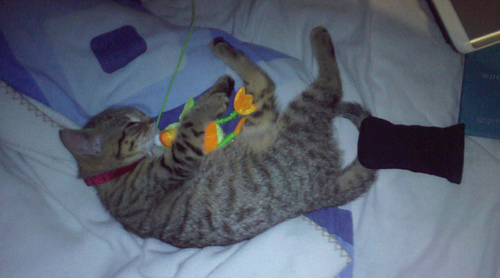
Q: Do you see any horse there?
A: No, there are no horses.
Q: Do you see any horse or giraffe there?
A: No, there are no horses or giraffes.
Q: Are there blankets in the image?
A: Yes, there is a blanket.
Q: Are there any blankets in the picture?
A: Yes, there is a blanket.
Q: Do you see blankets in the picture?
A: Yes, there is a blanket.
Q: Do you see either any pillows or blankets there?
A: Yes, there is a blanket.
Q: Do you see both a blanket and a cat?
A: Yes, there are both a blanket and a cat.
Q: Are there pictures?
A: No, there are no pictures.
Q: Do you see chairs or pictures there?
A: No, there are no pictures or chairs.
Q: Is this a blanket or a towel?
A: This is a blanket.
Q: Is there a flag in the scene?
A: No, there are no flags.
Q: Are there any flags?
A: No, there are no flags.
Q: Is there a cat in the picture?
A: Yes, there is a cat.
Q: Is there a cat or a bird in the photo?
A: Yes, there is a cat.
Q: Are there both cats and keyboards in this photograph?
A: No, there is a cat but no keyboards.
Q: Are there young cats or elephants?
A: Yes, there is a young cat.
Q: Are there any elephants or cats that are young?
A: Yes, the cat is young.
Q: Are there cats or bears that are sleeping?
A: Yes, the cat is sleeping.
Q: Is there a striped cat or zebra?
A: Yes, there is a striped cat.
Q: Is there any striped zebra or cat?
A: Yes, there is a striped cat.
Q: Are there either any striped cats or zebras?
A: Yes, there is a striped cat.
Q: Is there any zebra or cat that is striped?
A: Yes, the cat is striped.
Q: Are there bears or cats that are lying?
A: Yes, the cat is lying.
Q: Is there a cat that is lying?
A: Yes, there is a cat that is lying.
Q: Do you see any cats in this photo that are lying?
A: Yes, there is a cat that is lying.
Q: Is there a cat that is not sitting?
A: Yes, there is a cat that is lying.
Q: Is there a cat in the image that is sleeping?
A: Yes, there is a cat that is sleeping.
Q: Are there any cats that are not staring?
A: Yes, there is a cat that is sleeping.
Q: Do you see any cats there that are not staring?
A: Yes, there is a cat that is sleeping .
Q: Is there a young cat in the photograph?
A: Yes, there is a young cat.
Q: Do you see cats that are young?
A: Yes, there is a young cat.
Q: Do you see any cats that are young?
A: Yes, there is a cat that is young.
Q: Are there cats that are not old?
A: Yes, there is an young cat.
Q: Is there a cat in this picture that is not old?
A: Yes, there is an young cat.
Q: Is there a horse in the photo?
A: No, there are no horses.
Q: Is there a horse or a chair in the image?
A: No, there are no horses or chairs.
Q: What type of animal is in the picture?
A: The animal is a cat.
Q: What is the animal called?
A: The animal is a cat.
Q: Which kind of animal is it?
A: The animal is a cat.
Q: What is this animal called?
A: This is a cat.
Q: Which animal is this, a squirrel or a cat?
A: This is a cat.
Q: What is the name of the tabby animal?
A: The animal is a cat.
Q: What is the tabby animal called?
A: The animal is a cat.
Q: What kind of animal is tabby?
A: The animal is a cat.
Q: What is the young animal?
A: The animal is a cat.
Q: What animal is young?
A: The animal is a cat.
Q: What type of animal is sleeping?
A: The animal is a cat.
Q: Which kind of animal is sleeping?
A: The animal is a cat.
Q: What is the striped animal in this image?
A: The animal is a cat.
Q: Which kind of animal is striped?
A: The animal is a cat.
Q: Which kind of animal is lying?
A: The animal is a cat.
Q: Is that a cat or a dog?
A: That is a cat.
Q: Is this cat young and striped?
A: Yes, the cat is young and striped.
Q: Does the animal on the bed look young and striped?
A: Yes, the cat is young and striped.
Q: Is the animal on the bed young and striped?
A: Yes, the cat is young and striped.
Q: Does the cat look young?
A: Yes, the cat is young.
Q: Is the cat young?
A: Yes, the cat is young.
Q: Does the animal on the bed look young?
A: Yes, the cat is young.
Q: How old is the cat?
A: The cat is young.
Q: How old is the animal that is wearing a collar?
A: The cat is young.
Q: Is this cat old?
A: No, the cat is young.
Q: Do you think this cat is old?
A: No, the cat is young.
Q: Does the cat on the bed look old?
A: No, the cat is young.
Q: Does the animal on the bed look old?
A: No, the cat is young.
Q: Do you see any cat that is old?
A: No, there is a cat but it is young.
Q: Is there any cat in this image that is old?
A: No, there is a cat but it is young.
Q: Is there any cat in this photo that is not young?
A: No, there is a cat but it is young.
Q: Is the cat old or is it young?
A: The cat is young.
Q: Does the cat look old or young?
A: The cat is young.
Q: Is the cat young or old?
A: The cat is young.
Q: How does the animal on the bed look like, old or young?
A: The cat is young.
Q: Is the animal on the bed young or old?
A: The cat is young.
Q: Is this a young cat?
A: Yes, this is a young cat.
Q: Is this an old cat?
A: No, this is a young cat.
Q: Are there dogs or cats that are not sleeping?
A: No, there is a cat but it is sleeping.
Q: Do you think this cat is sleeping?
A: Yes, the cat is sleeping.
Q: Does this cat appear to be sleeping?
A: Yes, the cat is sleeping.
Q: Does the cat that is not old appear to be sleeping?
A: Yes, the cat is sleeping.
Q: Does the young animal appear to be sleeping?
A: Yes, the cat is sleeping.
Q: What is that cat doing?
A: The cat is sleeping.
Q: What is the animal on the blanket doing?
A: The cat is sleeping.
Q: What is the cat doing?
A: The cat is sleeping.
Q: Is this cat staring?
A: No, the cat is sleeping.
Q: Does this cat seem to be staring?
A: No, the cat is sleeping.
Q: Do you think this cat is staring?
A: No, the cat is sleeping.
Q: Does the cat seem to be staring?
A: No, the cat is sleeping.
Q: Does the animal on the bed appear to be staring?
A: No, the cat is sleeping.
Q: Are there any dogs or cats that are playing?
A: No, there is a cat but it is sleeping.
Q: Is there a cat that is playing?
A: No, there is a cat but it is sleeping.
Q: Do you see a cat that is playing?
A: No, there is a cat but it is sleeping.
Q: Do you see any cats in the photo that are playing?
A: No, there is a cat but it is sleeping.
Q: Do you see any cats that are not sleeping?
A: No, there is a cat but it is sleeping.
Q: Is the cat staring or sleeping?
A: The cat is sleeping.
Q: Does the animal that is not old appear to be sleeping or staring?
A: The cat is sleeping.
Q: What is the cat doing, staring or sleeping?
A: The cat is sleeping.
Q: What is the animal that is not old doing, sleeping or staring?
A: The cat is sleeping.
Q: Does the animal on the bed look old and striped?
A: No, the cat is striped but young.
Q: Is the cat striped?
A: Yes, the cat is striped.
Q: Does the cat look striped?
A: Yes, the cat is striped.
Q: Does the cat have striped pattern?
A: Yes, the cat is striped.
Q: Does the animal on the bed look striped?
A: Yes, the cat is striped.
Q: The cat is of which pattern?
A: The cat is striped.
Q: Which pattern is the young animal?
A: The cat is striped.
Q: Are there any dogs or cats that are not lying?
A: No, there is a cat but it is lying.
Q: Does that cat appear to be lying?
A: Yes, the cat is lying.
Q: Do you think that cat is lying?
A: Yes, the cat is lying.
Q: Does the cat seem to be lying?
A: Yes, the cat is lying.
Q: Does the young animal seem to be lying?
A: Yes, the cat is lying.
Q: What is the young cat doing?
A: The cat is lying.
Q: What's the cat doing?
A: The cat is lying.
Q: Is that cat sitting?
A: No, the cat is lying.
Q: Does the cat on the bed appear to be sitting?
A: No, the cat is lying.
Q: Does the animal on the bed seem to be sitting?
A: No, the cat is lying.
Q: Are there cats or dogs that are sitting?
A: No, there is a cat but it is lying.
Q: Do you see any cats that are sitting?
A: No, there is a cat but it is lying.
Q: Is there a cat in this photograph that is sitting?
A: No, there is a cat but it is lying.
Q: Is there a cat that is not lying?
A: No, there is a cat but it is lying.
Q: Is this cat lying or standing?
A: The cat is lying.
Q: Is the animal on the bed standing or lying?
A: The cat is lying.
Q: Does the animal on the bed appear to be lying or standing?
A: The cat is lying.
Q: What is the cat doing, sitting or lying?
A: The cat is lying.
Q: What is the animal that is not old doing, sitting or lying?
A: The cat is lying.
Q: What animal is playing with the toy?
A: The cat is playing with the toy.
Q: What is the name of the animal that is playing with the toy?
A: The animal is a cat.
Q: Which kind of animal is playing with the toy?
A: The animal is a cat.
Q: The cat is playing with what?
A: The cat is playing with a toy.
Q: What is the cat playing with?
A: The cat is playing with a toy.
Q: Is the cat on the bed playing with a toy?
A: Yes, the cat is playing with a toy.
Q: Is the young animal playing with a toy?
A: Yes, the cat is playing with a toy.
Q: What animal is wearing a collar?
A: The cat is wearing a collar.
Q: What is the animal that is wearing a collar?
A: The animal is a cat.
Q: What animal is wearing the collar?
A: The animal is a cat.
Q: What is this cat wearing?
A: The cat is wearing a collar.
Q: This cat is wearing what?
A: The cat is wearing a collar.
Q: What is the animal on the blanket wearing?
A: The cat is wearing a collar.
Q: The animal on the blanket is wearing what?
A: The cat is wearing a collar.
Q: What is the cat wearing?
A: The cat is wearing a collar.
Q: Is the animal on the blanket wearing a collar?
A: Yes, the cat is wearing a collar.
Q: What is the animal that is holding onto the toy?
A: The animal is a cat.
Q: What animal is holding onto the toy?
A: The animal is a cat.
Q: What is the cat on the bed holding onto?
A: The cat is holding onto the toy.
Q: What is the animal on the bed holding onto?
A: The cat is holding onto the toy.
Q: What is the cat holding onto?
A: The cat is holding onto the toy.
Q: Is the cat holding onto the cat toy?
A: Yes, the cat is holding onto the toy.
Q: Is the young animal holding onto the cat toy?
A: Yes, the cat is holding onto the toy.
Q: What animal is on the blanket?
A: The cat is on the blanket.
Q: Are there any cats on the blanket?
A: Yes, there is a cat on the blanket.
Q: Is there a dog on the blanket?
A: No, there is a cat on the blanket.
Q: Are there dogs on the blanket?
A: No, there is a cat on the blanket.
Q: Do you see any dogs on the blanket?
A: No, there is a cat on the blanket.